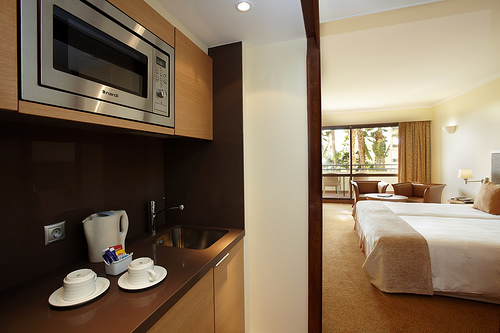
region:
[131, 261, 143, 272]
White mug on saucer.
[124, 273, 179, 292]
White saucer under mug.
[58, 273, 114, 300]
White mug on saucer.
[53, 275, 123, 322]
White saucer under mug.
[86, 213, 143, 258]
White pitcher sitting on counter.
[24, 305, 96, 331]
Counter top is dark brown.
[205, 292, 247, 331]
Brown wood cupboards in room.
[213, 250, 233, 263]
Silver handle on cupboard.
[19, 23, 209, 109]
Silver built in microwave in room.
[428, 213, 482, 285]
White bedspread on bed.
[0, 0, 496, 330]
Hotel room with a kitchenette.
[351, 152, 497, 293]
Two beds side by side.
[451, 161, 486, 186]
Lamp with a white shade on the wall.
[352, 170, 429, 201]
A table and chairs near the window.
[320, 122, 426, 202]
A sliding glass door behind the table.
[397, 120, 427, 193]
Brown drapes on the glass door.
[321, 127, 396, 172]
Palm trees outside of the glass door.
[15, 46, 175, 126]
A metal microwave with a black door.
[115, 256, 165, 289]
A cup on top of a small white plate.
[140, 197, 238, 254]
A sink at the edge of the countertop.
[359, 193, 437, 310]
tan blanket at the foot of the bed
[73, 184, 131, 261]
white pitcher on a counter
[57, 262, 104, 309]
upside down coffe mug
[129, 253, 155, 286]
upside down coffee mug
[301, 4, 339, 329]
wood framing on a wall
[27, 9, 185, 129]
silver microwave mounted in a cabinet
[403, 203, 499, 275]
white blanket on a bed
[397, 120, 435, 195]
long curtains on the window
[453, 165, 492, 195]
mounted wall bedside lamp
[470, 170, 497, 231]
brown pillows on the bed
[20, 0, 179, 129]
Built in silver microwave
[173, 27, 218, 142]
Brown wooden kitchen cabinet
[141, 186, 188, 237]
Silver metallic water faucet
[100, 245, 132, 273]
Ceramic holder containing packets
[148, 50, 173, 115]
Microwave control panel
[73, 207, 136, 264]
White ceramic water pitcher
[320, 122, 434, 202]
Window with drapes pulled back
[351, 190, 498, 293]
Brown and white bed comforter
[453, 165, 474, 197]
Lamp with cream shade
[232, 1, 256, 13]
Recessed light in ceiling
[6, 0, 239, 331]
this hotel room has a mini kitchen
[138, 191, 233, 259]
the sink of the hotel room's mini kitchen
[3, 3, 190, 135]
this hotel room has a microwave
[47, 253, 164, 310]
coffee cups set out by the hotel staff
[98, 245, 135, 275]
little sugar caddy for the hotel patrons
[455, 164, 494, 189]
bedside lamp in a hotel room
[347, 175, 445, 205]
this hotel room has a table and chairs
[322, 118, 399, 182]
this hotel room has a nice view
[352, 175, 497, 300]
this hotel room has a big bed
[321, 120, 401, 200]
this hotel room has an outdoor patio